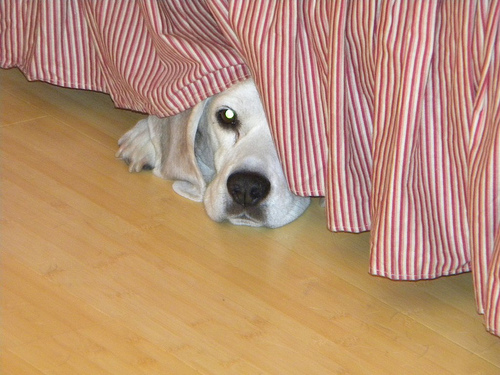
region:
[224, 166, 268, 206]
black nose of a white dog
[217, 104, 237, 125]
eye of a white dog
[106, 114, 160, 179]
paw of a white dog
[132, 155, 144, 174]
white toenail on a white dog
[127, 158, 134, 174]
white toenail on a white dog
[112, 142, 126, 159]
white toenail on a white dog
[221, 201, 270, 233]
mouth of a white dog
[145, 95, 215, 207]
large ear of a white dog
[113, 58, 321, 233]
white dog hiding under a curtain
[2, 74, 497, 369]
floor is light colored bamboo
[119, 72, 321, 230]
puppy hiding under a table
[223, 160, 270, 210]
nose of puppy is black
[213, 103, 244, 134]
eye of puppy is glistening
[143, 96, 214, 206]
long floppy ear of puppy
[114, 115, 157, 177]
small little claws on puppy's paw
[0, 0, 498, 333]
red and white striped tablecloth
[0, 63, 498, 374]
a wooden floor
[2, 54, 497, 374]
puppy lying on wooden floor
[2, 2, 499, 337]
puppy hiding underneath a red and white tablecloth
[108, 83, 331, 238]
puppy is hiding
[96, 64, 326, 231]
dog peeking out from under the bed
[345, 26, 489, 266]
red and white bed skirt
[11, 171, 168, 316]
wooden floor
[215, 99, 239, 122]
reflection of light in the dog's eye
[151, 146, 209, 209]
dog's ear is laying folded on the ground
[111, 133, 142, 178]
dog's nails are white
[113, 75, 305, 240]
dog is peeking his head out from under the bed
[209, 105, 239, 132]
dog's eye is brown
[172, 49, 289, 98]
bed skirt is laying on the dog's head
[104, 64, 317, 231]
PUPPY LAYING UNDER BED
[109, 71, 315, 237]
WHITE PUPPY LAYING UNDER BED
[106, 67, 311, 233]
PUPPLY LAYING ON WOODEN FLOOR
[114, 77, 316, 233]
WHITE PUPPY LAYING ON WOODEN FLOOR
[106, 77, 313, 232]
PUPPY PEEPING OUT FROM RED AND WHITE BED SKIRT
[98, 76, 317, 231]
WHITE PUPPY PEEPING OUT FROM RED AND WHITE BED SKIRT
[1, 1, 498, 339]
RED AND WHITE BED SKIRT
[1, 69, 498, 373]
WOODEN FLOOR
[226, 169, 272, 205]
PUPPYS BLACK NOSE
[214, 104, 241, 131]
PUPPYS BROWN EYE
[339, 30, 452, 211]
Red and white candy stripe.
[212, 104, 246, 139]
An eye for reflection.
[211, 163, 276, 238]
Black nose on a white dog.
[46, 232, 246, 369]
Wood flooring.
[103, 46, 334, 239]
A pooch peeks out.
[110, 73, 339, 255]
The white puppy under the candy-striped cover.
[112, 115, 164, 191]
The paw of a puppy.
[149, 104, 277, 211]
Eye, ear and nose.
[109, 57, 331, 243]
A white canine at rest.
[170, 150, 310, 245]
black and white nose of dog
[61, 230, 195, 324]
brown floor in room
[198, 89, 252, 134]
eye of the dog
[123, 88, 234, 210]
ear of the dog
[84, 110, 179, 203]
paw of the dog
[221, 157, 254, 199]
a nose on the dog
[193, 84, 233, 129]
an eye on the dog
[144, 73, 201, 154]
an ear on the dog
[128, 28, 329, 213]
a dog under the bed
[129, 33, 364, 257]
a dog on the floor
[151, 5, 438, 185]
a red and white skirt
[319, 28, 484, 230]
a bed skirt is red and white